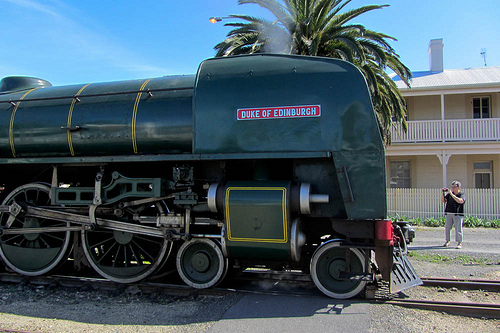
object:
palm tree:
[207, 0, 416, 150]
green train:
[0, 50, 425, 302]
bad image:
[0, 0, 499, 328]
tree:
[209, 1, 416, 150]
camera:
[442, 187, 448, 191]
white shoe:
[444, 241, 450, 247]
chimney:
[427, 38, 445, 71]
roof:
[380, 65, 498, 92]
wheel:
[308, 237, 369, 299]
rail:
[0, 266, 499, 314]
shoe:
[455, 243, 462, 248]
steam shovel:
[381, 245, 426, 297]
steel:
[392, 297, 500, 318]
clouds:
[80, 25, 142, 63]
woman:
[438, 180, 468, 249]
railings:
[389, 184, 499, 227]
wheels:
[0, 184, 73, 279]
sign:
[237, 104, 321, 119]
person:
[438, 179, 467, 250]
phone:
[442, 188, 448, 192]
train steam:
[258, 0, 308, 56]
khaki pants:
[444, 213, 463, 242]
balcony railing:
[405, 116, 498, 143]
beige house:
[381, 38, 499, 227]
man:
[441, 181, 468, 249]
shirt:
[443, 193, 464, 213]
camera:
[442, 187, 448, 192]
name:
[236, 104, 321, 120]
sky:
[0, 1, 500, 85]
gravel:
[0, 278, 197, 333]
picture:
[0, 0, 500, 333]